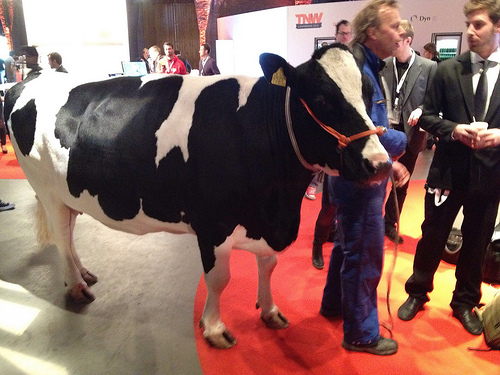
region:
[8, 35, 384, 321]
this is a cow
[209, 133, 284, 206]
the cow is black in color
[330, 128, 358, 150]
this is a belt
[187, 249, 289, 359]
these are the legs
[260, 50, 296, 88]
this is the ear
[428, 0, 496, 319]
this is a man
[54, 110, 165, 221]
this is the belly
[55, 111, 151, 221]
the belly is fat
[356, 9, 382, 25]
this is the hair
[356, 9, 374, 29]
the hair is long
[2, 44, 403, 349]
large cow in middle of room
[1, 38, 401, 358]
large cow is black and white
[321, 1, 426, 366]
man in blue holding leash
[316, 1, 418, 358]
man in blue guiding cow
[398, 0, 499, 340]
man in black suit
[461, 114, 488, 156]
man holding coffee cup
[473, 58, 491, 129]
man wearing black tie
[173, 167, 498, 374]
red carpet on the floor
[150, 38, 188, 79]
man wearing red hoodie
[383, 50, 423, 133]
man wearing tag on lanyard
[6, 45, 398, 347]
cow next to a man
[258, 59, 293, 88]
tag in cow's ear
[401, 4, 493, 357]
man in a suit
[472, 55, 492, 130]
tie on the man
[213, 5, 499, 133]
board behind the men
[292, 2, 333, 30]
lettering on the board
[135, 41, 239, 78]
group of people behind desk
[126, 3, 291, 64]
wood panels on wall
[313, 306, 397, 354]
shoes on the man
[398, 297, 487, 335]
shoes on man in suit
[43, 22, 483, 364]
a cow in a building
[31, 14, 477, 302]
this cow looks out of place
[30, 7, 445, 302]
this man is holding the cow with a leash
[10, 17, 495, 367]
this picture has been altered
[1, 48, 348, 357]
the cow is black and white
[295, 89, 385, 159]
the harness is orange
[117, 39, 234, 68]
people in the background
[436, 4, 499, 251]
this man looks inquisitive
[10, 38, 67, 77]
these people are looking at something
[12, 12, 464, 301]
a cow at a job expo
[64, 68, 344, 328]
this is a cow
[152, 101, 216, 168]
the cow is white and black in color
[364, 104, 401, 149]
this is a rope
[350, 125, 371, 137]
the rope is red in color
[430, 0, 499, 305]
this is a man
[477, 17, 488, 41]
the man is light skinned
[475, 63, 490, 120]
this is a neck tie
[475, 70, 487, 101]
the neck tie is black in color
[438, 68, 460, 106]
this is a coat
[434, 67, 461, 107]
the coat is black in color